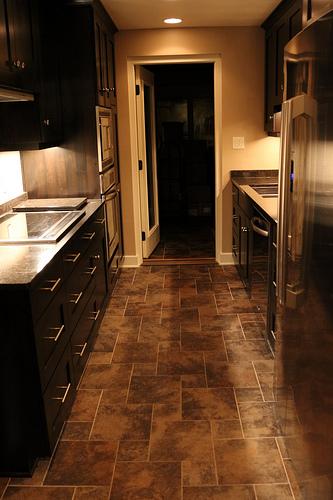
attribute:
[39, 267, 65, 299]
handle — silver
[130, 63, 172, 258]
door — ajar, open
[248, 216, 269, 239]
handle — silver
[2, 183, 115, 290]
counter — marble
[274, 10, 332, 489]
refrigerator — chrome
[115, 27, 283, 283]
wall — beige, tan, painted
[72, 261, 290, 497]
floor — tiled, brown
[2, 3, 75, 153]
cabinets — black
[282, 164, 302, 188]
light — blue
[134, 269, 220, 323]
tiles — brown, tan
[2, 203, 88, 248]
range — flat, ceramic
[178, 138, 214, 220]
boxes — stacked